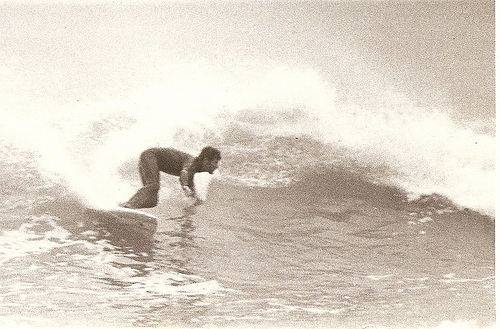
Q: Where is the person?
A: In the water.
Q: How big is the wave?
A: Large.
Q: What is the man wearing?
A: A wet suit.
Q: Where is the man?
A: In the ocean.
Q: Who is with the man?
A: The man is alone.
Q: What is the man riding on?
A: A surfboard.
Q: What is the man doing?
A: Surfing.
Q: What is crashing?
A: A wave.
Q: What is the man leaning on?
A: A surfboard.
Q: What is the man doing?
A: Surfing.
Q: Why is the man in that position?
A: Leverage.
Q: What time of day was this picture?
A: Afternoon.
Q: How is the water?
A: Rough.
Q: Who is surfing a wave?
A: A man.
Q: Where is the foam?
A: On the water.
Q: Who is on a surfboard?
A: A man.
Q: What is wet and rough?
A: Waves.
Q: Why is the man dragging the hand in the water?
A: For balance.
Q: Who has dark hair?
A: The surfer.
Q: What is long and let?
A: Pants.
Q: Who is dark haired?
A: The person.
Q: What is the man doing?
A: Surfing.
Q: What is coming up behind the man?
A: A wave.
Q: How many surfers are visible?
A: One.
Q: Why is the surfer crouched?
A: To keep his balance.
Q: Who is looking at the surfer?
A: The photographer.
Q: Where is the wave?
A: Behind the surfer.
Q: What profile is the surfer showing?
A: His right.